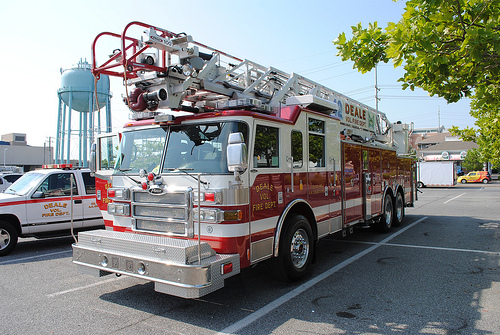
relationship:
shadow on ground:
[99, 215, 499, 335] [0, 179, 498, 334]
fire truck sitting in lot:
[68, 19, 421, 299] [4, 186, 497, 335]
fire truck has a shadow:
[68, 19, 421, 299] [99, 215, 499, 335]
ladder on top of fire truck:
[90, 20, 396, 147] [68, 19, 421, 299]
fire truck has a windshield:
[68, 19, 421, 299] [110, 121, 252, 177]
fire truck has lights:
[68, 19, 421, 299] [106, 187, 222, 225]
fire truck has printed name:
[68, 19, 421, 299] [251, 182, 279, 213]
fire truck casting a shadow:
[68, 19, 421, 299] [99, 215, 499, 335]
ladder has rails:
[90, 20, 396, 147] [89, 20, 168, 82]